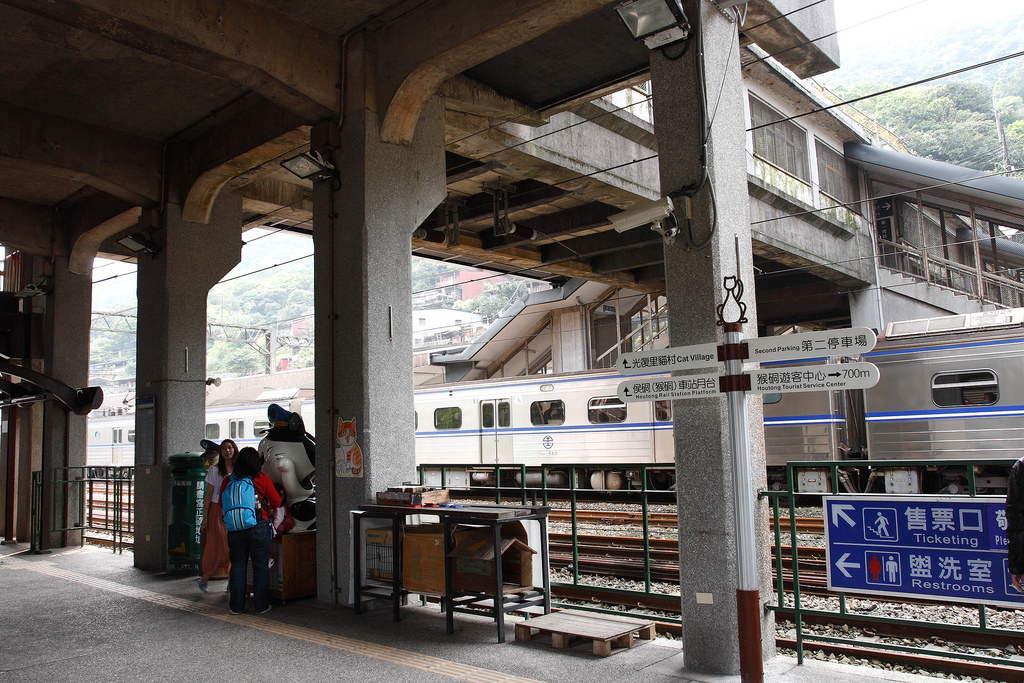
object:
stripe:
[85, 406, 1024, 450]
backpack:
[221, 473, 257, 531]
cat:
[715, 275, 747, 326]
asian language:
[616, 326, 881, 402]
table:
[351, 504, 551, 644]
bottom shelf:
[365, 520, 538, 597]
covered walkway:
[243, 41, 1024, 328]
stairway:
[879, 236, 1024, 314]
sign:
[822, 496, 1024, 609]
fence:
[28, 459, 1024, 669]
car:
[87, 307, 1024, 496]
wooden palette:
[515, 609, 654, 660]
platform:
[0, 542, 1024, 683]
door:
[480, 398, 513, 465]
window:
[929, 368, 998, 410]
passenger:
[217, 446, 280, 615]